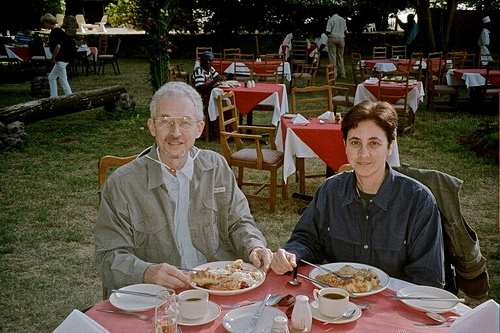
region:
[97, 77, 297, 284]
Man sit eating a meal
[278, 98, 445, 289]
Lady sitting eating a meal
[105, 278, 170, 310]
Saucer sitting on table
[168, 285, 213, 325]
Cup sitting on a saucer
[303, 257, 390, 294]
Plate full of food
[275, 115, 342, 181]
Red and white tablecloth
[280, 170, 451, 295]
Dark blue shirt on woman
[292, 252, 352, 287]
Silverwear on woman's plate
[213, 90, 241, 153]
Back of wooden chair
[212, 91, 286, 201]
Wooden chair sitting on the grass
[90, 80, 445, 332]
father and daughter eating breakfast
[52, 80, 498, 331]
man and woman enjoying breakfast outdoors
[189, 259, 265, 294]
breakfast food served on white china plate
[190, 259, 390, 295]
two white china plates on table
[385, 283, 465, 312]
stainless steel butter knife on top of white plate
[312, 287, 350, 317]
coffee in a white cup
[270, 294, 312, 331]
salt and pepper shakers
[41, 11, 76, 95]
woman in black shirt walking across the lawn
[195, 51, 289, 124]
man sitting at the table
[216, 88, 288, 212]
empty wooden chair at the table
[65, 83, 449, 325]
two people eating at a table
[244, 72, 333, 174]
table with red and white table cloths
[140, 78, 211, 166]
man wearing eyeglasses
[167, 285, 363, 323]
two coffee cups with white saucers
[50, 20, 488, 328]
tables set up in an outdoor venue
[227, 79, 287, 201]
brown wooden chairs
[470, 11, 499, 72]
person wearing a chefs uniform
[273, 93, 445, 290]
woman wearing a button down blue shirt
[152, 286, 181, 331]
clear glass of water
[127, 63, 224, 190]
man with white hair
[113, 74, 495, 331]
Two people sitting at a table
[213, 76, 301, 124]
Table with red and white tablecloth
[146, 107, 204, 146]
A man with wire rimmed glasses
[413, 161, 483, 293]
Green vest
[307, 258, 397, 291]
A white plate with food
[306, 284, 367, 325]
A white cup and saucer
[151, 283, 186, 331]
A clear drinking glass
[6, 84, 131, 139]
A log to sit on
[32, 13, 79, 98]
A person with white pants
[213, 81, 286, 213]
A wooden chair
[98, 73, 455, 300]
two people sitting at table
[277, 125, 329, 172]
red and white table cloth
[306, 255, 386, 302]
food on white plate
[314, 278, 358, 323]
coffee cup on saucer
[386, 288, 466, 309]
knife across white plate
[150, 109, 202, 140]
glasses on man's face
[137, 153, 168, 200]
collar on man's shirt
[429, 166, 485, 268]
green vest on chair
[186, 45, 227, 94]
person in striped shirt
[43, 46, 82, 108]
person walking in white pants